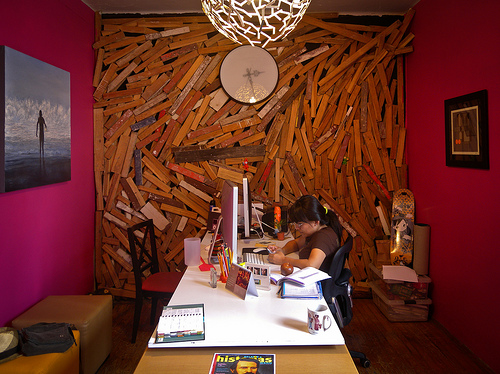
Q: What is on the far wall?
A: A clock.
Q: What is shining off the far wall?
A: Light.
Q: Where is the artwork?
A: On the wall.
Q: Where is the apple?
A: On the table.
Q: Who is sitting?
A: The woman.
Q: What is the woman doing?
A: Sitting at the table.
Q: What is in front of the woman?
A: A computer screen.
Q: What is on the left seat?
A: A red cushion.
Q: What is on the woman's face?
A: Glasses.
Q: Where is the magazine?
A: End of table.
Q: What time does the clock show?
A: 2:27.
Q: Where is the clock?
A: Wall with boards.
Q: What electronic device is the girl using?
A: Computer.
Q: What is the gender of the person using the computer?
A: Female.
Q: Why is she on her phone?
A: Texting.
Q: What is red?
A: Wall.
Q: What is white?
A: Table.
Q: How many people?
A: One.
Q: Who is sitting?
A: Girl.